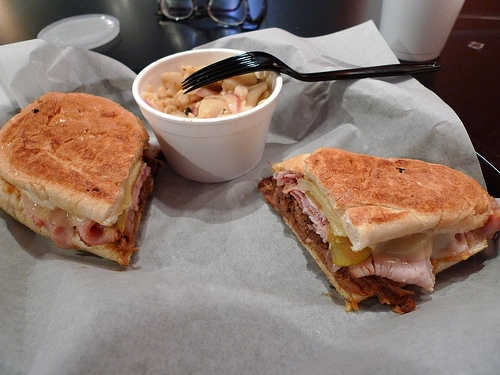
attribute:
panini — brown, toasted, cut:
[260, 148, 500, 315]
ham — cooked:
[275, 169, 500, 293]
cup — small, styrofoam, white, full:
[133, 46, 281, 185]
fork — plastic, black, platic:
[180, 50, 443, 97]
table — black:
[3, 1, 499, 374]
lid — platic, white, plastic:
[37, 13, 120, 51]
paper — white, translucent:
[0, 19, 499, 372]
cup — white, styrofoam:
[380, 0, 464, 65]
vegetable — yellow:
[326, 226, 371, 267]